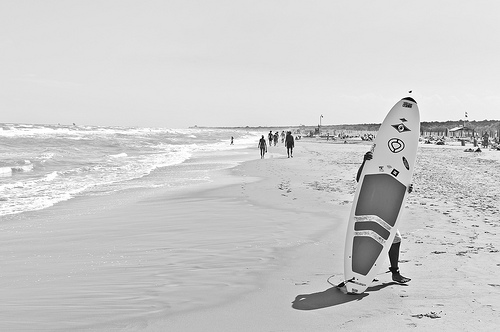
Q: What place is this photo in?
A: It is at the beach.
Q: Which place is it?
A: It is a beach.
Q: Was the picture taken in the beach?
A: Yes, it was taken in the beach.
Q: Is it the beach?
A: Yes, it is the beach.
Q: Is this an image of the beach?
A: Yes, it is showing the beach.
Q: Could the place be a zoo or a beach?
A: It is a beach.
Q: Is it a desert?
A: No, it is a beach.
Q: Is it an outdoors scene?
A: Yes, it is outdoors.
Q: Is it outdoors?
A: Yes, it is outdoors.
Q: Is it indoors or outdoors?
A: It is outdoors.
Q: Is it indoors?
A: No, it is outdoors.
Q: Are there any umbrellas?
A: No, there are no umbrellas.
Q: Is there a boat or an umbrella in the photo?
A: No, there are no umbrellas or boats.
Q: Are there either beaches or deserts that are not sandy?
A: No, there is a beach but it is sandy.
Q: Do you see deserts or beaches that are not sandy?
A: No, there is a beach but it is sandy.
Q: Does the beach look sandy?
A: Yes, the beach is sandy.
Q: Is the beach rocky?
A: No, the beach is sandy.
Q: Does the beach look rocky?
A: No, the beach is sandy.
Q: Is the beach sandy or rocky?
A: The beach is sandy.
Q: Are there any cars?
A: No, there are no cars.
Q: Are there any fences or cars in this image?
A: No, there are no cars or fences.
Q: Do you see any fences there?
A: No, there are no fences.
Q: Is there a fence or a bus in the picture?
A: No, there are no fences or buses.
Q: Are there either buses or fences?
A: No, there are no fences or buses.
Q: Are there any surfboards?
A: Yes, there is a surfboard.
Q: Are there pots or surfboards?
A: Yes, there is a surfboard.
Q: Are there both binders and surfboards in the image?
A: No, there is a surfboard but no binders.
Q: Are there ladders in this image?
A: No, there are no ladders.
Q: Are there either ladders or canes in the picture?
A: No, there are no ladders or canes.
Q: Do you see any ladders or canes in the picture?
A: No, there are no ladders or canes.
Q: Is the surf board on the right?
A: Yes, the surf board is on the right of the image.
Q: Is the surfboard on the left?
A: No, the surfboard is on the right of the image.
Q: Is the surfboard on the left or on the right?
A: The surfboard is on the right of the image.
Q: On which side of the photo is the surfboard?
A: The surfboard is on the right of the image.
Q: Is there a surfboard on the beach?
A: Yes, there is a surfboard on the beach.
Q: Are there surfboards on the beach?
A: Yes, there is a surfboard on the beach.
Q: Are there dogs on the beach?
A: No, there is a surfboard on the beach.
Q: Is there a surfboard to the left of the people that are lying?
A: Yes, there is a surfboard to the left of the people.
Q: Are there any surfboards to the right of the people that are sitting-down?
A: No, the surfboard is to the left of the people.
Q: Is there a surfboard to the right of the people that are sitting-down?
A: No, the surfboard is to the left of the people.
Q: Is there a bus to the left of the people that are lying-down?
A: No, there is a surfboard to the left of the people.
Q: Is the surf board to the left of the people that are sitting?
A: Yes, the surf board is to the left of the people.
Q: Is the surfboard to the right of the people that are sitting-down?
A: No, the surfboard is to the left of the people.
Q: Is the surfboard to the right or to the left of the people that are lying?
A: The surfboard is to the left of the people.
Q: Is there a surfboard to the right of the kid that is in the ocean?
A: Yes, there is a surfboard to the right of the child.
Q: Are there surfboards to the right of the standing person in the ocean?
A: Yes, there is a surfboard to the right of the child.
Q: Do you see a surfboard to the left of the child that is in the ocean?
A: No, the surfboard is to the right of the kid.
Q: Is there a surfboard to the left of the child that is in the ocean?
A: No, the surfboard is to the right of the kid.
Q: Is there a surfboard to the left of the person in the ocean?
A: No, the surfboard is to the right of the kid.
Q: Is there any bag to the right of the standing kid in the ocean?
A: No, there is a surfboard to the right of the child.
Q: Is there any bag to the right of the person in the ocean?
A: No, there is a surfboard to the right of the child.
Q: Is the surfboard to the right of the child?
A: Yes, the surfboard is to the right of the child.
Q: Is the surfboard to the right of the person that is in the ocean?
A: Yes, the surfboard is to the right of the child.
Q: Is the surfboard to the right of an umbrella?
A: No, the surfboard is to the right of the child.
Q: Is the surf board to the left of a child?
A: No, the surf board is to the right of a child.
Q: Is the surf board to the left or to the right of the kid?
A: The surf board is to the right of the kid.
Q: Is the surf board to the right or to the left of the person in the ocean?
A: The surf board is to the right of the kid.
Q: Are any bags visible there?
A: No, there are no bags.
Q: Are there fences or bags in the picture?
A: No, there are no bags or fences.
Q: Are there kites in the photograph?
A: No, there are no kites.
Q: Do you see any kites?
A: No, there are no kites.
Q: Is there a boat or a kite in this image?
A: No, there are no kites or boats.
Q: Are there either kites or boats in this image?
A: No, there are no kites or boats.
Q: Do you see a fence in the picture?
A: No, there are no fences.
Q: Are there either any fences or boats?
A: No, there are no fences or boats.